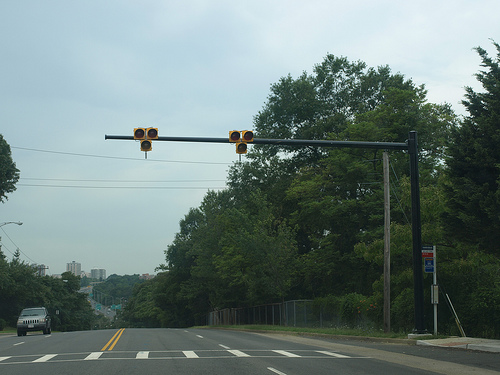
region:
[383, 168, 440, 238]
white lines leading to the sign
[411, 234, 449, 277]
blue and red sign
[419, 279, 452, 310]
small silver box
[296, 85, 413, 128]
very large green trees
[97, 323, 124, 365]
double yellow lines in middle of streer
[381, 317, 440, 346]
small concrete base on post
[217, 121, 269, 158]
yellow traffic signal across street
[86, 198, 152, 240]
over cast gray skies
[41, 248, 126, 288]
tall buildings in the far distance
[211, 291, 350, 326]
tall section of silver fence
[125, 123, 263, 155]
traffic signal lights with metal post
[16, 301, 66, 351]
a car is running on the road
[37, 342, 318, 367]
pedestrian crossing on the road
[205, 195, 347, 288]
lot of trees with branches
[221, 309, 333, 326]
steel fencing near the road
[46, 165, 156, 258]
sky with clouds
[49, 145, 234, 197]
electric cables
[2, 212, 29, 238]
street light with metal pole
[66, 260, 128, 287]
big building behind the trees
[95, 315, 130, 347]
road marked with yellow line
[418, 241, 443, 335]
a sign on the sidewalk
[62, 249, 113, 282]
a building at the bottom of the hill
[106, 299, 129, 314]
a roadsign over the street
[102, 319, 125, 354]
a yellow line on the road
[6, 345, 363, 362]
a crosswalk across the street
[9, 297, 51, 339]
a car on the road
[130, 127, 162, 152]
the light fixture is yellow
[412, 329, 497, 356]
the sidewalk is concrete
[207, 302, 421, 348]
a fence along the road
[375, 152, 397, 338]
a telephone pole by the fence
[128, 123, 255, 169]
Traffic signal with three lights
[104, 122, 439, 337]
A long black color steel pole which holds traffic light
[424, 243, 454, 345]
Sign board on the road side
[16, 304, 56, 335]
A car is moving on the road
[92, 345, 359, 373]
Sign indicating pedestrian cross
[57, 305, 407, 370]
unfortunately the long road is empty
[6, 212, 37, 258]
Lamp post besides the road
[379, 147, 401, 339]
A tall electrical post holding the cable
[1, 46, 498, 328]
Trees are on the either side of the road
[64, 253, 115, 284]
Tall buildings are on the back side of the road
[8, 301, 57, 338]
a car on the street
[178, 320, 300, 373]
white center lines on the road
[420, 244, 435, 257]
the sign is red and blue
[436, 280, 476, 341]
metal on the cords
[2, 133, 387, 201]
the power lines go across the street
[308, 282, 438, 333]
plants growing across the fence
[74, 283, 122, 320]
a street going through the trees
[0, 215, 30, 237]
a lightpole over the street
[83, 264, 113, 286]
buildings in the distance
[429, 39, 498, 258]
a tree behind the fence